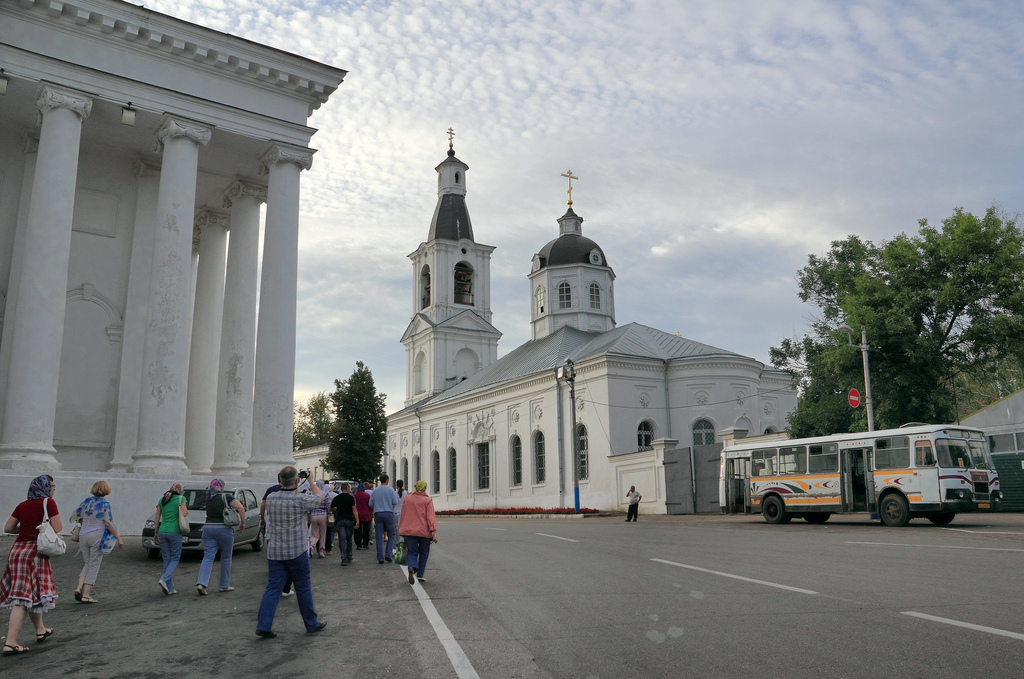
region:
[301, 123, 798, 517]
a large white church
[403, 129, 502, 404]
tower on the church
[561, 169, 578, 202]
cross on the dome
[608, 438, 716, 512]
a white wall outside the church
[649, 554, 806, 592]
white line on road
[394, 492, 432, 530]
the jacket is pink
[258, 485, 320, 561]
the shirt is plaid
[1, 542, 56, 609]
the dress is plaid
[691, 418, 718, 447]
window on church facing street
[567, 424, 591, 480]
window on church facing street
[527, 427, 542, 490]
window on church facing street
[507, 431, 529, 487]
window on church facing street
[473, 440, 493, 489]
window on church facing street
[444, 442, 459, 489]
window on church facing street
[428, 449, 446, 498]
window on church facing street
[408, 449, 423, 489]
window on church facing street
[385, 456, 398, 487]
window on church facing street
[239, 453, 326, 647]
man walking on a street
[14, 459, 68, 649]
woman walking on a street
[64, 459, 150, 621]
woman walking on a street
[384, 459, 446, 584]
woman walking on a street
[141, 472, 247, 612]
women walking on street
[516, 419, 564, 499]
window on a building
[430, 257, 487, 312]
window on a building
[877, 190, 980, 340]
tree near a building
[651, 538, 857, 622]
line on a street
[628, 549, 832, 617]
a white line in the road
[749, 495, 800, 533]
the front tire of the bus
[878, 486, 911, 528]
it is the back tire of the bus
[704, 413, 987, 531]
it is a white city bus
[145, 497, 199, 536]
the shirt is green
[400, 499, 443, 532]
the jacket is red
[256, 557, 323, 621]
the jeans are blue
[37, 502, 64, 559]
a white bag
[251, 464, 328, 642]
a tourist with a camera wearing jeans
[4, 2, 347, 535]
a white roman style building with columns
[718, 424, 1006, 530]
a white and orange colored bus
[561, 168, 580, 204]
a golden cross on top of a church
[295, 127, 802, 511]
a white stone church with towers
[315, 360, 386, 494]
the leaves of a tree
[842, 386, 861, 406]
a do not enter sign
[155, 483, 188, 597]
a woman with a green shirt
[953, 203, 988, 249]
green leaves on the tree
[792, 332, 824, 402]
green leaves on the tree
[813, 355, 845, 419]
green leaves on the tree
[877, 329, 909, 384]
green leaves on the tree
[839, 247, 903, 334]
green leaves on the tree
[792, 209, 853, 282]
green leaves on the tree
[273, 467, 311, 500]
the head of a man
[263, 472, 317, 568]
the shirt of a man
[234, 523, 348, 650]
the pants of a man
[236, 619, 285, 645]
the left foot of a man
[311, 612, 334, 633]
the right foot of a man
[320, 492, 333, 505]
the elbow of a man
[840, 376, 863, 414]
The red sign on the pole.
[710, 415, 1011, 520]
The yellow and white bus.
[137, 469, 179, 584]
The woman walking in a green shirt.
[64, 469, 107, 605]
The older woman walking with a blue shirt.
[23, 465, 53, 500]
The scarf on the womans head.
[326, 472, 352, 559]
The man with a black shirt.